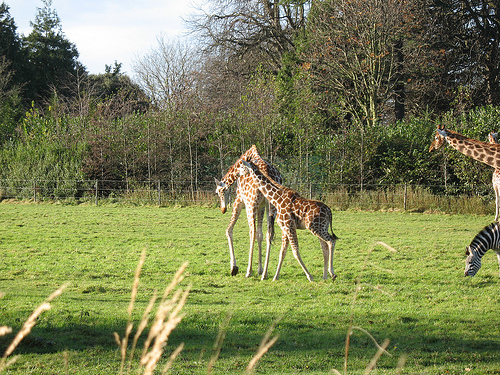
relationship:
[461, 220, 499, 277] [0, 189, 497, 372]
animal eating grass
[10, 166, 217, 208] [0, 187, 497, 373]
fence surrounding area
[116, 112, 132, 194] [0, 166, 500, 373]
tree behind enclosure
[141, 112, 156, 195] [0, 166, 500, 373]
tree behind enclosure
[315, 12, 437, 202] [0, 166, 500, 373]
tree behind enclosure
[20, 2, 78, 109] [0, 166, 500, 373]
tree behind enclosure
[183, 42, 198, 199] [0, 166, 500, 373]
tree behind enclosure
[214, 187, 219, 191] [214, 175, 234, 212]
marking on head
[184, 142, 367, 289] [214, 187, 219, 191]
giraffe has marking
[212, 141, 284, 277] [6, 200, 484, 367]
animal in field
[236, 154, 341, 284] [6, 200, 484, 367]
animal in field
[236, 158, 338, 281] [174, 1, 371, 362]
animal in center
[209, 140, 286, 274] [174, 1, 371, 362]
animal in center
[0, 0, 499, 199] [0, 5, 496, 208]
trees in background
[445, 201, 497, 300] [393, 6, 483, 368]
zebra in center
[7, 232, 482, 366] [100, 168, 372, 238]
plants in front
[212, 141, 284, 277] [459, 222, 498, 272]
animal with zebra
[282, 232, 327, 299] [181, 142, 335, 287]
leg on giraffe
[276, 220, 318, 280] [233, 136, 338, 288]
leg on giraffe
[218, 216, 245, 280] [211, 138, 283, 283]
leg on giraffe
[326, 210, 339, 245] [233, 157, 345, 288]
tail on giraffe